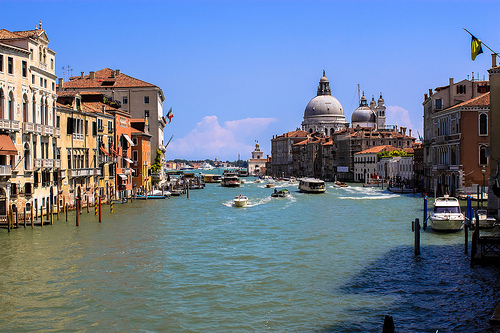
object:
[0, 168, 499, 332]
river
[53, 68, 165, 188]
building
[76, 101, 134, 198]
building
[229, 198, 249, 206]
boat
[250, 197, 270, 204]
wake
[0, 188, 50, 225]
dock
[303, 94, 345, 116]
dome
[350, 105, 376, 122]
dome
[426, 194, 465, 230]
boat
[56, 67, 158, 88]
roof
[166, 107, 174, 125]
flags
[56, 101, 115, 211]
building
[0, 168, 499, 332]
canal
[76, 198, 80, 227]
pole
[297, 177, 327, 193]
vaporetto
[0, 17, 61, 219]
houses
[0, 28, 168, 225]
row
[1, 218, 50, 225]
waterfront